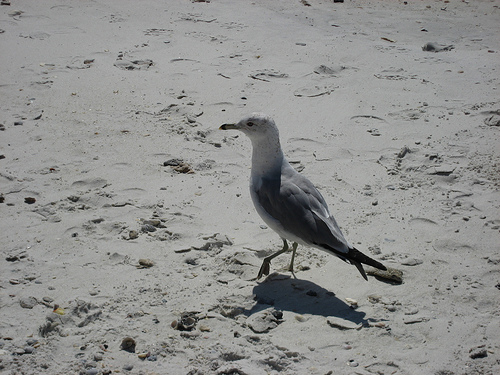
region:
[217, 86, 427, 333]
a bird on the sand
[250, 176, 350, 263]
bird's feathers are gray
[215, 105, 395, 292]
A seagull stands on the sand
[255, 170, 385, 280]
Gray wing of a seagull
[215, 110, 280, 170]
Head of a seagull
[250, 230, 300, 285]
Seagull's feet in the sand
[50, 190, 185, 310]
Gray sand with rocks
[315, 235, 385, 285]
A seagull's tail feather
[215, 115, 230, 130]
Black tip of a seagull's beak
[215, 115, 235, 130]
The beak of a seagull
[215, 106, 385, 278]
A bird walking on the beach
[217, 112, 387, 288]
A gray bird walks on the beach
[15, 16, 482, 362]
gray sand with surface of depressions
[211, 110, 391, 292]
seagull walking on sand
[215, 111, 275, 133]
straight beak in front of beady eye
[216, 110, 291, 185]
light feathers over head and neck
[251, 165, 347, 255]
body shaped like a teardrop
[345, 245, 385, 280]
dark tail feathers split in different directions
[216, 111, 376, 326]
shadow directly under bird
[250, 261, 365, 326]
triangular shape of shadow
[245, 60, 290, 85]
curved depression in sand with circles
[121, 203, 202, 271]
dark pebbles on sand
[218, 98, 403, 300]
this is a bird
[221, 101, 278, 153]
this is a head of a bird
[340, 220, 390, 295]
this is the tail a bird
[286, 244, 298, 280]
this is a leg of a bird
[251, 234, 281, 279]
this is the leg of a bird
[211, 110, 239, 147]
this is the beakof a bird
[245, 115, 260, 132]
this i the eye of a bird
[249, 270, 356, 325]
this is shadow of a bird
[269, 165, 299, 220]
this are feathers of a bird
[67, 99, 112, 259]
this is the ground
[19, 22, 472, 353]
photograph taken at the beach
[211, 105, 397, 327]
grey and white sea gull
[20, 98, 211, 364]
shells and rocks in the sand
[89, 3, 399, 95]
foot prints in the sand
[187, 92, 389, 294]
bird with one leg off the ground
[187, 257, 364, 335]
shadow of sea gull on sand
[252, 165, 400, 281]
grey and white feathers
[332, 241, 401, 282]
two longer tail feathers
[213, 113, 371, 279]
bird on the sand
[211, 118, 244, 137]
beak of the bird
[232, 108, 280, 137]
head of the bird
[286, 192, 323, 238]
wing of the bird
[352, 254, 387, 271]
tail of the bird